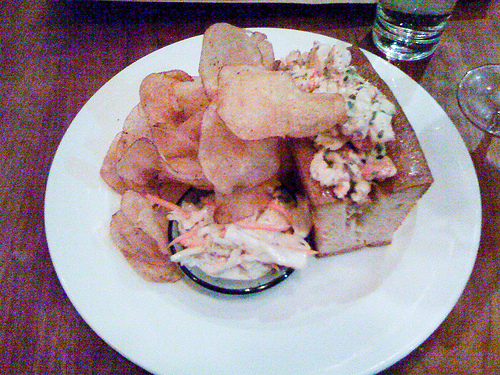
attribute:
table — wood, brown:
[4, 2, 495, 372]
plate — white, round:
[39, 14, 490, 375]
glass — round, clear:
[455, 59, 499, 141]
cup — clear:
[369, 1, 461, 62]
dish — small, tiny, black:
[164, 174, 310, 297]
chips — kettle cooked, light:
[87, 16, 337, 224]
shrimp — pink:
[308, 142, 348, 187]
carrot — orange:
[147, 190, 196, 249]